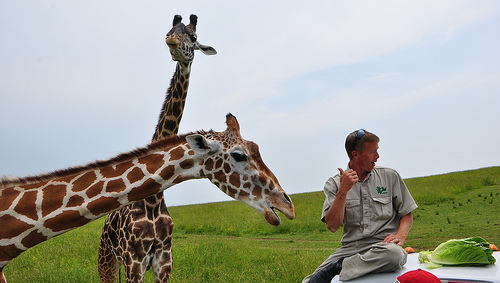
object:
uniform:
[302, 166, 419, 283]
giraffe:
[0, 113, 295, 282]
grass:
[0, 165, 500, 282]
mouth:
[271, 206, 292, 223]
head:
[184, 113, 295, 227]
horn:
[172, 14, 183, 25]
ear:
[194, 41, 218, 56]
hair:
[2, 130, 207, 187]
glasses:
[349, 129, 369, 148]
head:
[346, 129, 382, 174]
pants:
[301, 240, 407, 283]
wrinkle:
[358, 253, 383, 264]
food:
[419, 235, 499, 270]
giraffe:
[97, 13, 217, 282]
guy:
[301, 128, 420, 283]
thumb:
[337, 167, 346, 175]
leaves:
[417, 236, 499, 270]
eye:
[189, 35, 197, 43]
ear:
[183, 134, 220, 154]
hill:
[0, 166, 499, 283]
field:
[0, 164, 499, 278]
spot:
[14, 192, 38, 220]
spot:
[43, 184, 66, 217]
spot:
[71, 172, 96, 192]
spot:
[98, 162, 136, 178]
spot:
[139, 153, 166, 174]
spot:
[170, 147, 185, 161]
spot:
[180, 160, 195, 171]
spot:
[159, 164, 177, 181]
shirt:
[321, 164, 417, 241]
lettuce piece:
[415, 236, 499, 269]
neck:
[1, 132, 205, 270]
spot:
[44, 211, 93, 233]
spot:
[2, 213, 34, 239]